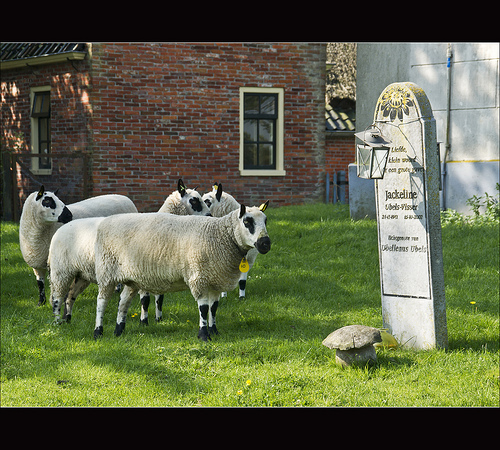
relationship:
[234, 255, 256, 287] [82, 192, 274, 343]
tag on animal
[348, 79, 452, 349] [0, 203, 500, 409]
headstone sticking area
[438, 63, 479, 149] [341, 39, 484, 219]
trees on building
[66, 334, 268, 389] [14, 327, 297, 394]
shadows on area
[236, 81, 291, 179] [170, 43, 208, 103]
frame on building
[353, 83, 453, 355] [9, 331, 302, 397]
stone in grass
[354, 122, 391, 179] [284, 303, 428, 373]
lamp on grave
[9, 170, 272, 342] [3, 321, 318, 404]
sheep on grass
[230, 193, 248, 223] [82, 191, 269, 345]
ears on sheep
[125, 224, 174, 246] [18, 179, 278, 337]
wool on sheep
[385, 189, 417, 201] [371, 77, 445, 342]
letter on stone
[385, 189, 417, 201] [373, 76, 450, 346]
letter on stone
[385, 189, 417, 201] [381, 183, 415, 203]
letter on stone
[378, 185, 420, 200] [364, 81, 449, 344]
letter on stone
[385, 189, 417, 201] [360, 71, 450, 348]
letter on stone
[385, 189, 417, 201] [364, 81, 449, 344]
letter on stone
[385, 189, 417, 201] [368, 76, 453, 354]
letter on stone